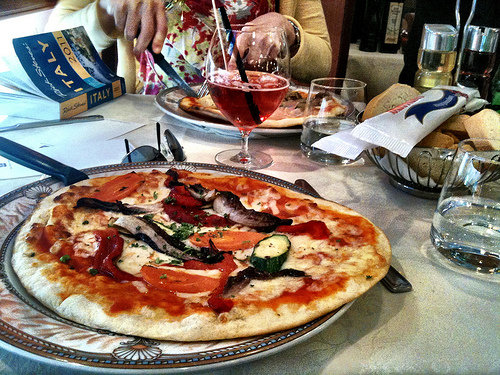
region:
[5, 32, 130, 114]
A guidebook about Italy.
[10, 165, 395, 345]
A pizza.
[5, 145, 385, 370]
The pizza is on a plate.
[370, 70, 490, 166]
A basket full of bread.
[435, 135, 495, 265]
A glass of water.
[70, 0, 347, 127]
The woman is eating the pizza with a knife and fork.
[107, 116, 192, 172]
A pair of sunglasses.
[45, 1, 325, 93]
The woman is wearing a yellow cardigan.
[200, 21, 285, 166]
A glass of juice.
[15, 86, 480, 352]
The table is covered in a tablecloth.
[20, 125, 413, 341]
whole pizza in middle of table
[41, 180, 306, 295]
cut vegetables on top of pizza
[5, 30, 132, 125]
travel book with some slightly open pages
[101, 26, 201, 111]
hand holding knife to cut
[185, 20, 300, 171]
wine goblet with red beverage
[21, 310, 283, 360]
plate with many borders and daisy motif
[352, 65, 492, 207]
basket of sliced bread with packaged food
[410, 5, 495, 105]
salad dressing in handled rack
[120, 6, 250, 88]
patterned blouse with red blobs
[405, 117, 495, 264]
transparent glass with water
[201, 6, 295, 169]
Pink drink in wine glass with black straw.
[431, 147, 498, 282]
Small glass water goblet.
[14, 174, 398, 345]
Personal pizza with cheese and toppings.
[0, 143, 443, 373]
Personal pan pizza on plate with shell design.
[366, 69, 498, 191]
Basket of bread on table.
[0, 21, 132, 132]
Blue and tan book about Italy 2011.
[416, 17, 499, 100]
Glass oil and vinegar containers with silver lids.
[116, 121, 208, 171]
Pair of black and gray sunglasses on table.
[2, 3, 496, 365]
Lady eating pizza at table.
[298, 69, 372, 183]
Small glass of water on table.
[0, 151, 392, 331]
A tasty vegetable pizza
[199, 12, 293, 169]
A cup of red sangria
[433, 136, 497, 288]
A glass with some water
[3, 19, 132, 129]
A guide of italy 2011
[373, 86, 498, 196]
A basket of bread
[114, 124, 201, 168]
An eyeglass near of the pizza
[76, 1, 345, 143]
A woman eating a pizza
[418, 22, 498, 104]
A bottle of oil and a bottle of vinegar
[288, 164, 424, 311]
A knife under the plate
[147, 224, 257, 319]
A couple of tomatoes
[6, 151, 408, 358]
A PIZZA ON A TRAY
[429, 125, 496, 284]
A GLASS OF WATER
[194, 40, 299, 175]
A DRINK IN A WINE GLASS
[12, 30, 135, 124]
A BOOK ABOUT ITALY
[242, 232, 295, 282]
A PIECE OF SQUASH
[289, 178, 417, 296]
A BUTTER KNIFE ON THE TABLE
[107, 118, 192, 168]
A PAIR OF SUNGLASSES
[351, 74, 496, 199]
A BREAD BASKET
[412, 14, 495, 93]
OIL AND VINEGAR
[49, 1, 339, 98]
SOMEONE CUTTING A PIZZA